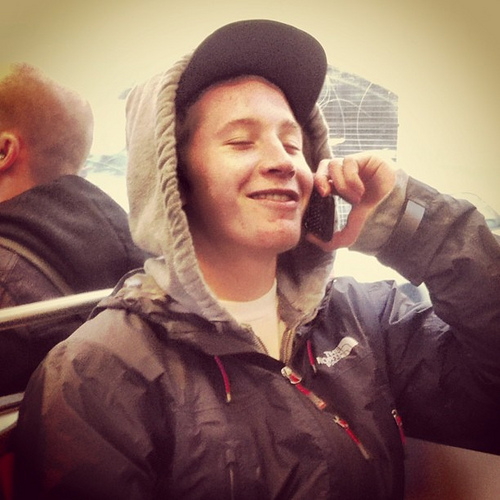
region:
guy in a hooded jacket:
[19, 15, 495, 498]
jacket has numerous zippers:
[276, 363, 409, 468]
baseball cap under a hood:
[115, 13, 330, 282]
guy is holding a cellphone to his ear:
[168, 69, 338, 261]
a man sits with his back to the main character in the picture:
[4, 60, 161, 400]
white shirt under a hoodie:
[207, 270, 292, 382]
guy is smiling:
[173, 65, 328, 270]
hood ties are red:
[204, 327, 322, 404]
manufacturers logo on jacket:
[308, 328, 363, 369]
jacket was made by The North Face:
[310, 334, 362, 371]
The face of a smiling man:
[194, 88, 311, 248]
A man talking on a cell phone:
[191, 78, 379, 257]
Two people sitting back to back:
[11, 47, 386, 427]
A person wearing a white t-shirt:
[210, 213, 291, 340]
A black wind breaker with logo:
[116, 315, 418, 480]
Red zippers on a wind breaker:
[277, 356, 373, 461]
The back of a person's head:
[13, 61, 100, 171]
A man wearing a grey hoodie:
[128, 26, 326, 321]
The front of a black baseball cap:
[165, 17, 327, 106]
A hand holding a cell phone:
[314, 147, 389, 247]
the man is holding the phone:
[102, 26, 388, 301]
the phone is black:
[267, 163, 386, 303]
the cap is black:
[122, 21, 362, 193]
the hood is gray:
[103, 30, 414, 440]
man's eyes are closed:
[170, 123, 370, 247]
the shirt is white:
[215, 268, 311, 358]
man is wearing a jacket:
[81, 48, 465, 480]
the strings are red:
[188, 346, 448, 423]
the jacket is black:
[53, 225, 493, 471]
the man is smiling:
[160, 87, 481, 300]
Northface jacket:
[313, 339, 375, 381]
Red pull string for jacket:
[176, 328, 289, 427]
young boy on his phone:
[123, 71, 391, 253]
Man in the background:
[9, 71, 121, 226]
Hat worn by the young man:
[176, 25, 434, 93]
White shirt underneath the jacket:
[228, 286, 304, 370]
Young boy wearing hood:
[98, 63, 204, 285]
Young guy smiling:
[197, 106, 320, 233]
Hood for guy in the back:
[9, 186, 126, 283]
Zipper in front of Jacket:
[205, 438, 247, 495]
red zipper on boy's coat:
[277, 362, 332, 414]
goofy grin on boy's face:
[237, 178, 309, 211]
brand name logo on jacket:
[307, 328, 364, 373]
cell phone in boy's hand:
[297, 170, 349, 255]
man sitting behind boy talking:
[0, 50, 165, 332]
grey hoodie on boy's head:
[114, 5, 358, 343]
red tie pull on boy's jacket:
[204, 352, 237, 413]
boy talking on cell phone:
[12, 6, 497, 493]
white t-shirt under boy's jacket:
[197, 272, 322, 390]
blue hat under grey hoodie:
[172, 7, 332, 123]